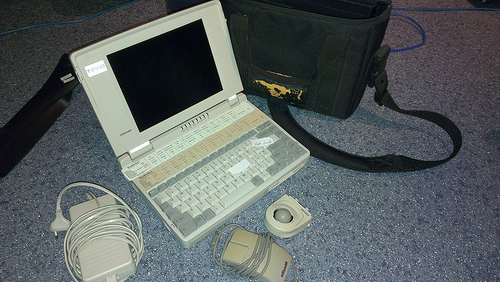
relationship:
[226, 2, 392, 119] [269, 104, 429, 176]
bag with strap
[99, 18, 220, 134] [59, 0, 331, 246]
screen on laptop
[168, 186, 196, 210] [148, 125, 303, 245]
keys on keyboard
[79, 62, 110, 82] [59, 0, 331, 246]
label on laptop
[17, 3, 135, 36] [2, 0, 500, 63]
cord in background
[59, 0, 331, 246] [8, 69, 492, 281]
laptop on floor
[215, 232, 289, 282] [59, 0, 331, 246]
mouse for computer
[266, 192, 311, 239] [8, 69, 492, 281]
roller ball on floor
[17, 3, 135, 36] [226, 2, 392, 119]
cord behind bag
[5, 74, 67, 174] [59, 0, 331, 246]
strap behind laptop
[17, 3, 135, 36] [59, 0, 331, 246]
cord behind laptop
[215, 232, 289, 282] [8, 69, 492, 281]
mouse on floor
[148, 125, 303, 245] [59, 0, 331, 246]
keyboard on laptop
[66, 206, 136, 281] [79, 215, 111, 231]
adapter with cord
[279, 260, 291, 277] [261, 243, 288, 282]
writing on pad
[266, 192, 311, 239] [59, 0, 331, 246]
trackball for laptop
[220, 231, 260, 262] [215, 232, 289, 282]
buttons on mouse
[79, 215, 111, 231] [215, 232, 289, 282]
cord around mouse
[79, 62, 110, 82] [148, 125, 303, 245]
label for keyboard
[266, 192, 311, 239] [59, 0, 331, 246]
trackball of computer